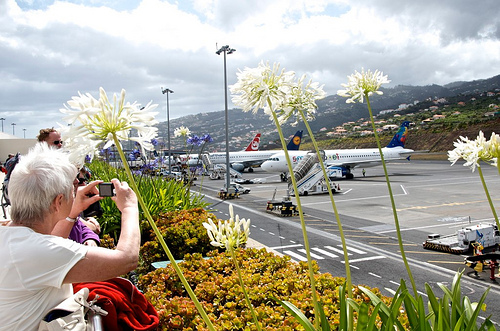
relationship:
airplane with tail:
[262, 123, 414, 184] [386, 119, 412, 148]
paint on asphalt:
[438, 214, 469, 224] [121, 160, 499, 330]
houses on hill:
[382, 122, 399, 133] [88, 72, 499, 161]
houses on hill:
[358, 128, 375, 136] [88, 72, 499, 161]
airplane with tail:
[135, 130, 263, 175] [244, 130, 261, 150]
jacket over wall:
[65, 274, 161, 330] [84, 213, 109, 330]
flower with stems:
[197, 133, 213, 145] [191, 144, 208, 178]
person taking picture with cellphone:
[1, 140, 142, 330] [98, 177, 115, 198]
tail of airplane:
[244, 130, 261, 150] [135, 130, 263, 175]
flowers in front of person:
[339, 66, 429, 327] [1, 140, 142, 330]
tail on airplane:
[386, 119, 412, 148] [262, 123, 414, 184]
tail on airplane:
[244, 130, 261, 150] [135, 130, 263, 175]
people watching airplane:
[36, 123, 62, 155] [262, 123, 414, 184]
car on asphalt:
[229, 183, 251, 194] [121, 160, 499, 330]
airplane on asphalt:
[262, 123, 414, 184] [121, 160, 499, 330]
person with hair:
[1, 140, 142, 330] [8, 140, 79, 224]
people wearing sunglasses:
[36, 123, 62, 155] [49, 139, 63, 144]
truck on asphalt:
[291, 162, 344, 198] [121, 160, 499, 330]